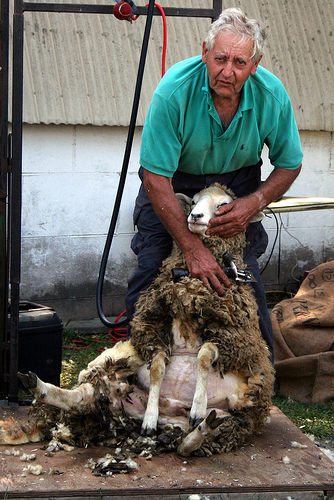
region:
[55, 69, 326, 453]
An old man shearing a sheep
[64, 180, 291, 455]
The sheep is in the process of being sheared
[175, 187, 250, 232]
The sheep looks complacent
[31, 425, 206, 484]
Shreds of fur on the table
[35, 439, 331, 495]
An unpolished wooden table beneath the sheep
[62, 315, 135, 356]
A thin red wire behind the man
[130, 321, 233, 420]
The sheep's two front legs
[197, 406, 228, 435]
The two forked toes on the sheep's foot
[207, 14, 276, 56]
The old man has short hair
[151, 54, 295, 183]
A light blue shirt on the old man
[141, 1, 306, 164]
man is looking in the camera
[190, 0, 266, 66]
the man`s hair is grey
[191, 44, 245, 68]
the eyes are open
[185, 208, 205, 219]
the nose is black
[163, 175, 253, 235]
the sheep face is white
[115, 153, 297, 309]
the man is shaving the sheep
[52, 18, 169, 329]
the hose is black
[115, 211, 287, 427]
the fur is matted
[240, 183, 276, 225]
a light spot on the man`s wrist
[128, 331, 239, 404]
the stomach is pinkish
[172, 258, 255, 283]
A razor in the man's hand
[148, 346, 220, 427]
The front legs of the sheep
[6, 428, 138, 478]
Shaved hair from the sheep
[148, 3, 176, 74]
A red wire behind the man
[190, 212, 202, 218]
The nose of the sheep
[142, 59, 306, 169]
The man is wearing a turquoise shirt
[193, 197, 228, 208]
The eyes of the sheep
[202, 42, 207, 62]
The right ear of the man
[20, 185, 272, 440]
A sheep being shaved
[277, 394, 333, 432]
Grass beside the sheep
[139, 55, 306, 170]
a teal short sleeve collard shirt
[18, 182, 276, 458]
a sheep sitting upright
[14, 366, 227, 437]
hooves of a sheep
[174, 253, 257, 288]
shaving shears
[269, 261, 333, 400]
a burlap sack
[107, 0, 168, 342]
a red hose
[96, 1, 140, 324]
a thick black hose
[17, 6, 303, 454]
a man sheering a sheep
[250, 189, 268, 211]
a wristwatch tan line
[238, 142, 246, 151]
dark blue emblem on teal shirt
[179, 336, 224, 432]
leg of a sheep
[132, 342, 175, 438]
leg of a sheep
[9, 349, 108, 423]
leg of a sheep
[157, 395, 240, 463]
leg of a sheep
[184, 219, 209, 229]
mouth of a sheep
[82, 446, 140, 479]
pile of dirty sheep wool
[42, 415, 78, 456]
pile of dirty sheep wool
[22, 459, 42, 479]
pile of dirty sheep wool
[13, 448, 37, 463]
pile of dirty sheep wool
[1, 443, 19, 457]
pile of dirty sheep wool